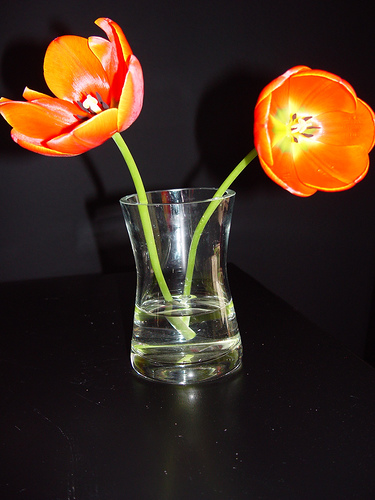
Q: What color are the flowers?
A: Orange.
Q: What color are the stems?
A: Green.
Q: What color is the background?
A: Black.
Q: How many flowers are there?
A: Two.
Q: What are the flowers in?
A: Water.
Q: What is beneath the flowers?
A: The table.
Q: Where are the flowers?
A: In the vase.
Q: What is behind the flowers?
A: A wall.